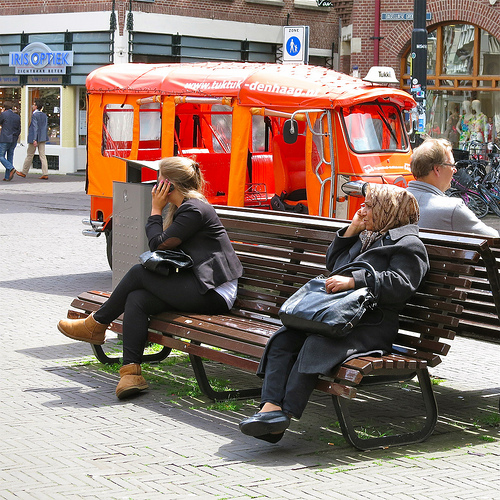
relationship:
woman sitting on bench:
[106, 168, 229, 303] [61, 203, 485, 455]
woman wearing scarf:
[237, 181, 429, 445] [368, 183, 421, 231]